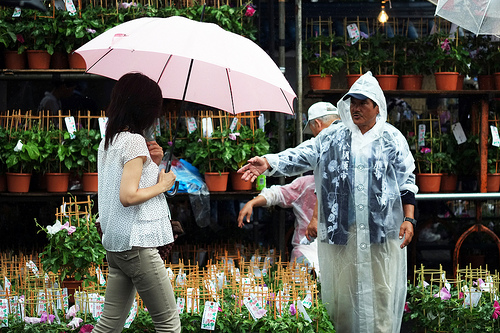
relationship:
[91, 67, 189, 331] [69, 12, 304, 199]
woman holding umbrella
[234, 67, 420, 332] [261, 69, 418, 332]
man wearing parka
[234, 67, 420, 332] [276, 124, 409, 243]
man wearing hawaiian shirt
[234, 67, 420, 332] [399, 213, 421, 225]
man wearing watch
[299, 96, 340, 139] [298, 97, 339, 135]
man in hat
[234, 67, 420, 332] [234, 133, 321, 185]
man extending arm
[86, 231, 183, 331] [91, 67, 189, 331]
pants on woman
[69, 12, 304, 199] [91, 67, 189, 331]
umbrella above woman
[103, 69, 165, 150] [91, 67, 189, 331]
hair on woman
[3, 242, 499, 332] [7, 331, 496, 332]
plants on ground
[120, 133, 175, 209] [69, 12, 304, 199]
arm holding umbrella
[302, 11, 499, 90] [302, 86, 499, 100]
plants on shelf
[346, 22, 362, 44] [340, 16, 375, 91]
tag on plant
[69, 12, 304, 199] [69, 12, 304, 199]
umbrella has umbrella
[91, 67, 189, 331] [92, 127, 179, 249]
woman wearing blouse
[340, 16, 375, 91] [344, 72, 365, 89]
plant in pot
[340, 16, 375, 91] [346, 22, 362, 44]
plant with tag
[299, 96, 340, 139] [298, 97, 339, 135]
man with hat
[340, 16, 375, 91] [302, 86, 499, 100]
plant on shelf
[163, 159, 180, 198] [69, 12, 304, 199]
handle of umbrella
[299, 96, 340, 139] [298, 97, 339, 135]
man wearing hat